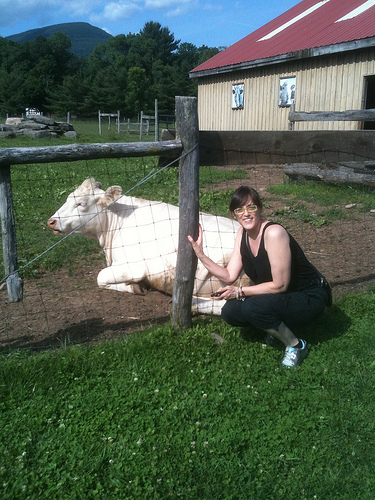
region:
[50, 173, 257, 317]
a cow is lying down in a pen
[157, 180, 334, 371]
a woman is stooping next to the cow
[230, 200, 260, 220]
the lady is wearing eyeglasses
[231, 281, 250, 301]
the girl is wearing bracelets on her wrist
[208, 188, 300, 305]
the lady has a cell phone in her hand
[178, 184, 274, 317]
the lady's hand is on the wooden post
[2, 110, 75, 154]
a pile of rocks is on the farm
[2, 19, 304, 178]
a green mountain is in the background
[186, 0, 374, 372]
a barn is behind the girl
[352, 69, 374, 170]
a door is open to the barn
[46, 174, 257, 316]
a white cow lying down on farm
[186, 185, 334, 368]
a woman posing in front of a cow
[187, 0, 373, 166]
a red-roofed barn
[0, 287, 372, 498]
a patch of green grass in front of a fence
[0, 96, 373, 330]
fence made of wood and wire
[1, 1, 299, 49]
partially clouded sky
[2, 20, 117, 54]
top of a small mountain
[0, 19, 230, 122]
big dark green trees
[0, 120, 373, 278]
grass behind a fence on a farm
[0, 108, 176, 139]
fences made of wood and wire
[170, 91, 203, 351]
grey wooden fence post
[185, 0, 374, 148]
side and roof of a barn building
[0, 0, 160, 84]
trees and a tall hilltop in front of a blue sky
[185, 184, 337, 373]
woman in a tank top crouching down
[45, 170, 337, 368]
woman posing next to a cow laying down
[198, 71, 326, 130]
two windows on a barn wall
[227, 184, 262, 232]
woman's face with glasses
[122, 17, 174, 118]
tall dark green trees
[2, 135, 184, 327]
cow behind a wood and wire fence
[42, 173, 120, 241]
white cow's head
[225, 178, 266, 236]
The woman is smiling.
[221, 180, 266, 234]
The woman is wearing glasses.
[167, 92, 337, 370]
The woman is leaning against a post.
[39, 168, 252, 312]
The cow is white.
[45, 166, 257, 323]
The cow is lying down.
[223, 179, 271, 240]
The woman has hair.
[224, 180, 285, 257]
The woman's hair is dark.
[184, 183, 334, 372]
The woman is wearing a shirt.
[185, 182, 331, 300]
The woman's shirt is sleeveless.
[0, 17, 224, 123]
The trees are green.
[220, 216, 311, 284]
woman's shirt is black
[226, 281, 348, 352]
woman's pants are black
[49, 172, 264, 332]
cow is laying down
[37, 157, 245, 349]
the cow is white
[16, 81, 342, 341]
the fence is brown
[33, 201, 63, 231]
cow's nose is pink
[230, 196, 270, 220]
woman is wearing eye glasses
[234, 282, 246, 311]
woman wearing a bracelet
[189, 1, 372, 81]
the roof is red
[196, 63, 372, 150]
the building is brown